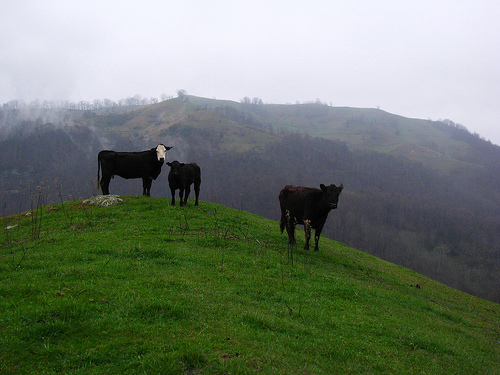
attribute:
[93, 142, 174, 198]
cow — black in color, black, standing, adult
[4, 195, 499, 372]
mountain — green in color, grassy, large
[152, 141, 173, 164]
face — white in color, white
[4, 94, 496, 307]
mountain — misty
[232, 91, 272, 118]
tree — in horizon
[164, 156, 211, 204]
cow — standing, black colored, calf, black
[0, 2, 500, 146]
sky — white in color, foggy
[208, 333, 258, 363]
dirt — clumped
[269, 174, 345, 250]
cow — black in color, big, black color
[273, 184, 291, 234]
tail — long